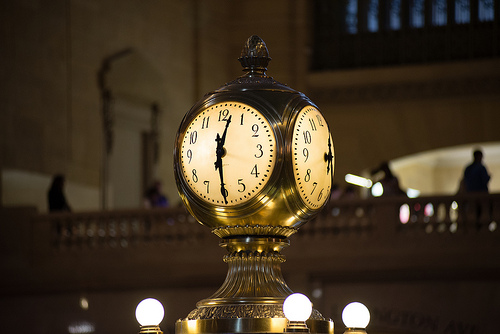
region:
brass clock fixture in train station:
[175, 31, 353, 328]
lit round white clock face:
[183, 105, 267, 208]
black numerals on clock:
[183, 101, 268, 201]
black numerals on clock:
[301, 111, 337, 198]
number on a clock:
[232, 107, 252, 125]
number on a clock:
[246, 117, 261, 137]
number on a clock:
[250, 141, 270, 162]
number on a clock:
[241, 162, 266, 177]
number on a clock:
[226, 175, 246, 195]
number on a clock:
[201, 176, 212, 197]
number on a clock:
[185, 165, 201, 185]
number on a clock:
[180, 146, 200, 161]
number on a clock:
[185, 130, 202, 145]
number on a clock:
[197, 110, 213, 132]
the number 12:
[216, 105, 229, 121]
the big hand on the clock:
[215, 133, 231, 205]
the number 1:
[240, 113, 245, 123]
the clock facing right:
[291, 103, 334, 212]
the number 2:
[250, 124, 257, 136]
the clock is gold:
[173, 35, 334, 330]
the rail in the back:
[10, 190, 497, 231]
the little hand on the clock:
[215, 117, 232, 166]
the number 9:
[184, 148, 194, 163]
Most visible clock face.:
[179, 102, 276, 211]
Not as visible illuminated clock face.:
[290, 104, 334, 210]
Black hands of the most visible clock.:
[213, 116, 230, 205]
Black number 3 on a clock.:
[255, 142, 263, 158]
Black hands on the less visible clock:
[323, 129, 333, 184]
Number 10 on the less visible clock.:
[302, 129, 311, 146]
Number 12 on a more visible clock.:
[217, 108, 231, 121]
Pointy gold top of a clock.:
[238, 33, 271, 69]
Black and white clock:
[174, 104, 269, 200]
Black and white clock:
[289, 98, 338, 220]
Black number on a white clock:
[212, 103, 232, 130]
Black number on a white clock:
[232, 106, 243, 133]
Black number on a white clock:
[247, 119, 267, 133]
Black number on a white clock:
[249, 142, 272, 160]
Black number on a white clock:
[243, 162, 273, 180]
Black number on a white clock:
[229, 171, 251, 199]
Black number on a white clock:
[212, 180, 236, 201]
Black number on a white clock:
[199, 174, 219, 202]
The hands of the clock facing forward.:
[205, 120, 242, 200]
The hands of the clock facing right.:
[316, 134, 334, 186]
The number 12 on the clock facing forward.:
[216, 111, 231, 125]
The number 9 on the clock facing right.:
[300, 138, 310, 163]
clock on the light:
[175, 100, 283, 210]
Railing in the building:
[6, 188, 496, 264]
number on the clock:
[207, 98, 244, 135]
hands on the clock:
[180, 120, 255, 196]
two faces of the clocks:
[155, 93, 362, 215]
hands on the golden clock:
[163, 107, 250, 214]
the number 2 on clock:
[234, 113, 271, 154]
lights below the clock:
[253, 251, 390, 332]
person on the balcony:
[338, 147, 428, 231]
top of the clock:
[203, 18, 296, 111]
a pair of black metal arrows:
[205, 112, 237, 209]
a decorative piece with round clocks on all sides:
[171, 56, 361, 239]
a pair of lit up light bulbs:
[278, 283, 380, 331]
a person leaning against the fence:
[31, 162, 86, 249]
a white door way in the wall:
[96, 89, 173, 229]